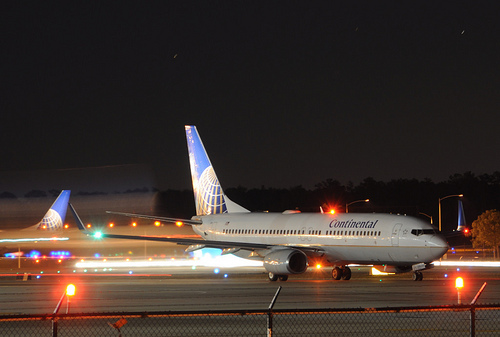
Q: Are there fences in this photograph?
A: Yes, there is a fence.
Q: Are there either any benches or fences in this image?
A: Yes, there is a fence.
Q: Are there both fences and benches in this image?
A: No, there is a fence but no benches.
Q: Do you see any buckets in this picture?
A: No, there are no buckets.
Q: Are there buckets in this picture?
A: No, there are no buckets.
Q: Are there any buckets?
A: No, there are no buckets.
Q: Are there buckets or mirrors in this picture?
A: No, there are no buckets or mirrors.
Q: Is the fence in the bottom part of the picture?
A: Yes, the fence is in the bottom of the image.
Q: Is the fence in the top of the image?
A: No, the fence is in the bottom of the image.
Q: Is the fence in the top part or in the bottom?
A: The fence is in the bottom of the image.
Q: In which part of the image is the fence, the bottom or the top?
A: The fence is in the bottom of the image.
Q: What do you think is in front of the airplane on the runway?
A: The fence is in front of the plane.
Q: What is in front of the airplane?
A: The fence is in front of the plane.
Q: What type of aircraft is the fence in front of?
A: The fence is in front of the airplane.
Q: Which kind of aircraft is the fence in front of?
A: The fence is in front of the airplane.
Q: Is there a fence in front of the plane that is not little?
A: Yes, there is a fence in front of the plane.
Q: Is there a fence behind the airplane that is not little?
A: No, the fence is in front of the plane.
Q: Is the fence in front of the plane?
A: Yes, the fence is in front of the plane.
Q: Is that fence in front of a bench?
A: No, the fence is in front of the plane.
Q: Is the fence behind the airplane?
A: No, the fence is in front of the airplane.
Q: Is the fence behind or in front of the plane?
A: The fence is in front of the plane.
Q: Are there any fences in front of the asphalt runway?
A: Yes, there is a fence in front of the runway.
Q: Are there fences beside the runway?
A: Yes, there is a fence beside the runway.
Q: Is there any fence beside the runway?
A: Yes, there is a fence beside the runway.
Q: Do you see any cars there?
A: No, there are no cars.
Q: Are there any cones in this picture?
A: No, there are no cones.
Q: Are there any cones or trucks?
A: No, there are no cones or trucks.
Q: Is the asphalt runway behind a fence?
A: Yes, the runway is behind a fence.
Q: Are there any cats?
A: No, there are no cats.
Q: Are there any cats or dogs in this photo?
A: No, there are no cats or dogs.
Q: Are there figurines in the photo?
A: No, there are no figurines.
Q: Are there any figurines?
A: No, there are no figurines.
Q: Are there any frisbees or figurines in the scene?
A: No, there are no figurines or frisbees.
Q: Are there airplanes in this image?
A: Yes, there is an airplane.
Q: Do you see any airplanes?
A: Yes, there is an airplane.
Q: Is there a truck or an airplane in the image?
A: Yes, there is an airplane.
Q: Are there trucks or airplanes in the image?
A: Yes, there is an airplane.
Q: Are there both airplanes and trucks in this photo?
A: No, there is an airplane but no trucks.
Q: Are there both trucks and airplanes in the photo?
A: No, there is an airplane but no trucks.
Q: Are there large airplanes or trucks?
A: Yes, there is a large airplane.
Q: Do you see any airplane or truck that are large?
A: Yes, the airplane is large.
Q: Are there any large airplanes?
A: Yes, there is a large airplane.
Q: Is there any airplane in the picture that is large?
A: Yes, there is an airplane that is large.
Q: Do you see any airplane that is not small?
A: Yes, there is a large airplane.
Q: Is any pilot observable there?
A: No, there are no pilots.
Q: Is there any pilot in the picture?
A: No, there are no pilots.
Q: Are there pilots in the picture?
A: No, there are no pilots.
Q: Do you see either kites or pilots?
A: No, there are no pilots or kites.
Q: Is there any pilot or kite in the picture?
A: No, there are no pilots or kites.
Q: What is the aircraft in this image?
A: The aircraft is an airplane.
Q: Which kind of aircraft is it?
A: The aircraft is an airplane.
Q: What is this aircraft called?
A: This is an airplane.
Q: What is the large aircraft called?
A: The aircraft is an airplane.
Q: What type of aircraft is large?
A: The aircraft is an airplane.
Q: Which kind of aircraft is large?
A: The aircraft is an airplane.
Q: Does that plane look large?
A: Yes, the plane is large.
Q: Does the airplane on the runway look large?
A: Yes, the airplane is large.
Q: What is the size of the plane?
A: The plane is large.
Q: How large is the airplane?
A: The airplane is large.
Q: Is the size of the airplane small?
A: No, the airplane is large.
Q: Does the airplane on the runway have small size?
A: No, the airplane is large.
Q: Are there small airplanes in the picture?
A: No, there is an airplane but it is large.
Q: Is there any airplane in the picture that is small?
A: No, there is an airplane but it is large.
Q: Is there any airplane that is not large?
A: No, there is an airplane but it is large.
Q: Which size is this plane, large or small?
A: The plane is large.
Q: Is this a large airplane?
A: Yes, this is a large airplane.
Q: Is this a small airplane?
A: No, this is a large airplane.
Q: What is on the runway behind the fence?
A: The plane is on the runway.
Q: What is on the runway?
A: The plane is on the runway.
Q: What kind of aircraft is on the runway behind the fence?
A: The aircraft is an airplane.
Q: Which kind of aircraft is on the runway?
A: The aircraft is an airplane.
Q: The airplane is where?
A: The airplane is on the runway.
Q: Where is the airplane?
A: The airplane is on the runway.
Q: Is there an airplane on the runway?
A: Yes, there is an airplane on the runway.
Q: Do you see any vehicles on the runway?
A: No, there is an airplane on the runway.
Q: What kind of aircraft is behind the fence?
A: The aircraft is an airplane.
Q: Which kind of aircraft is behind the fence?
A: The aircraft is an airplane.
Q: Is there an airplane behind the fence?
A: Yes, there is an airplane behind the fence.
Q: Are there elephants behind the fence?
A: No, there is an airplane behind the fence.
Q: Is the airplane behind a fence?
A: Yes, the airplane is behind a fence.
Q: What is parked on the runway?
A: The plane is parked on the runway.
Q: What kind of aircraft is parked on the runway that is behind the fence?
A: The aircraft is an airplane.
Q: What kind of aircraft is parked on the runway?
A: The aircraft is an airplane.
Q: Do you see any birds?
A: No, there are no birds.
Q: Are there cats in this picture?
A: No, there are no cats.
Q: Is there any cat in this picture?
A: No, there are no cats.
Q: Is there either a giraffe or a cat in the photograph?
A: No, there are no cats or giraffes.